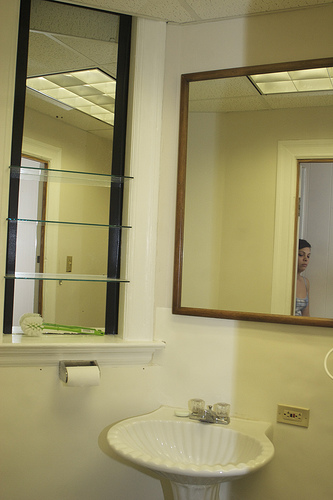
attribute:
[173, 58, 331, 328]
frame — brown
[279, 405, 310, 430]
electric outlet — white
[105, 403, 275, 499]
sink — white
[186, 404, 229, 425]
faucet — silver, closed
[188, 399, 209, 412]
faucet handle — clear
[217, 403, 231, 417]
faucet handle — clear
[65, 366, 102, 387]
toilet paper — white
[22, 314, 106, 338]
bathroom brush — green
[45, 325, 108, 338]
handle — green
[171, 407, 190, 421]
soap — white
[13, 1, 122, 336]
mirror — tall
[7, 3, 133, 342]
border — black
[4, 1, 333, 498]
bathroom — beige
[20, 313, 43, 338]
bristles — white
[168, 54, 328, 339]
mirror — framed, brown, large